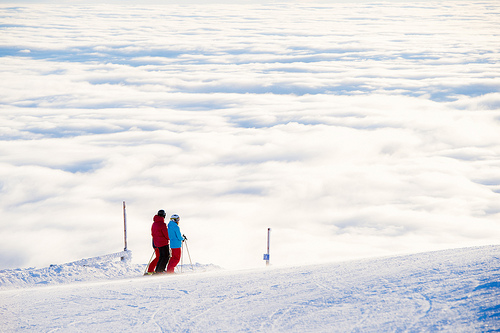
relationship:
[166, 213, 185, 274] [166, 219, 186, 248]
person in blue jacket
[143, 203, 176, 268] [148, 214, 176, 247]
man in coat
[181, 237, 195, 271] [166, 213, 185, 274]
pole in person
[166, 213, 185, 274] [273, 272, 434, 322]
person in snow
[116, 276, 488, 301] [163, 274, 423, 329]
ground covered snow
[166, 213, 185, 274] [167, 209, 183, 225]
person wearing helmet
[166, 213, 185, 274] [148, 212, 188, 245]
person wearing outfit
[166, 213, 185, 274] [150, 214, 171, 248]
person wearing coat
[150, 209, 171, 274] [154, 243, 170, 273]
man wearing pants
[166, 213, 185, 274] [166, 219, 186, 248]
person wearing blue jacket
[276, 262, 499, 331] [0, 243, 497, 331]
tracks in snow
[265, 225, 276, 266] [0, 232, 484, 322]
pole in snow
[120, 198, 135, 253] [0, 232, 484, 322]
pole in snow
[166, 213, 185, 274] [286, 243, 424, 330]
person at start of run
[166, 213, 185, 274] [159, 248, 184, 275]
person in pants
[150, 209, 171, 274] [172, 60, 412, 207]
man above clouds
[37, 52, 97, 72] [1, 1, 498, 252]
sky peaking through clouds